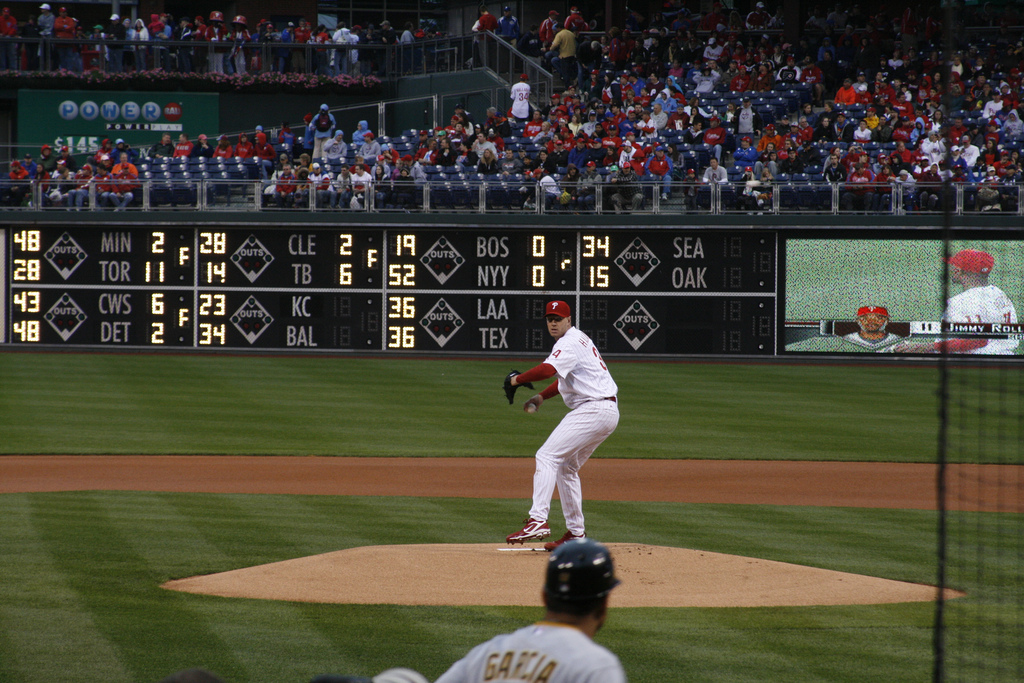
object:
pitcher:
[499, 298, 624, 554]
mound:
[195, 527, 838, 599]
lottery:
[52, 94, 187, 136]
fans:
[731, 133, 759, 172]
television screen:
[788, 236, 1024, 358]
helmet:
[536, 537, 624, 618]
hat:
[539, 298, 575, 320]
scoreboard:
[6, 230, 781, 358]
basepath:
[0, 451, 1022, 512]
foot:
[503, 514, 553, 545]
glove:
[499, 364, 535, 405]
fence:
[0, 178, 1022, 363]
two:
[421, 300, 637, 682]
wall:
[16, 258, 435, 314]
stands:
[5, 33, 1024, 212]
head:
[537, 297, 578, 340]